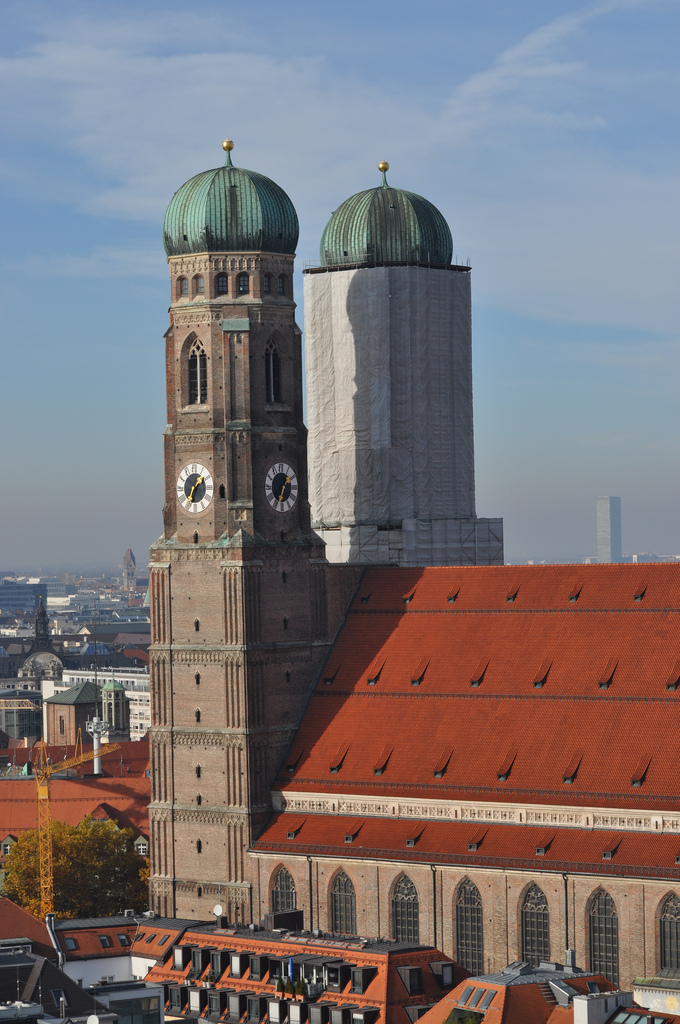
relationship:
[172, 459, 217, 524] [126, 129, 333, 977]
clock on building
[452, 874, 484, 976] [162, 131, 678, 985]
window on building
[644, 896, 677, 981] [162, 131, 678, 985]
window on building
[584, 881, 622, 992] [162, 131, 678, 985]
window on building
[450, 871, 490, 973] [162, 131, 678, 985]
window on building